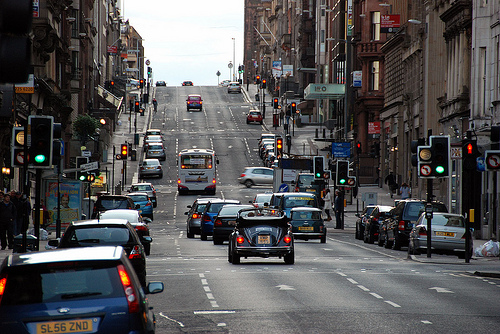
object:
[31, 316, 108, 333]
license plate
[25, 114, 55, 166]
stoplight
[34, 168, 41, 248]
pole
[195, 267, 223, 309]
lines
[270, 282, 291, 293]
arrow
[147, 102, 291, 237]
road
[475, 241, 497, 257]
trashbag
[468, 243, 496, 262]
curb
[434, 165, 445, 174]
light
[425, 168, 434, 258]
pole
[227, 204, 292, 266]
car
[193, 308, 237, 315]
manhole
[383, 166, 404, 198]
person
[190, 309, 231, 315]
line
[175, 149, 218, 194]
bus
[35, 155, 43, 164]
light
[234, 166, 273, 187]
car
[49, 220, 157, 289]
car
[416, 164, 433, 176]
sign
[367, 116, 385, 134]
sign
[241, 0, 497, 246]
buillding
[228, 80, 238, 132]
post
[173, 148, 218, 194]
cars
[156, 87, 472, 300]
street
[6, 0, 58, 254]
corner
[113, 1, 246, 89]
sky